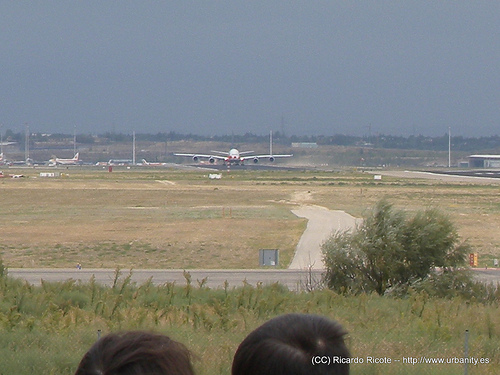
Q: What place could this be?
A: It is a desert.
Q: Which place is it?
A: It is a desert.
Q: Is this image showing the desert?
A: Yes, it is showing the desert.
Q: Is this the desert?
A: Yes, it is the desert.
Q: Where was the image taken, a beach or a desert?
A: It was taken at a desert.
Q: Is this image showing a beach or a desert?
A: It is showing a desert.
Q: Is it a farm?
A: No, it is a desert.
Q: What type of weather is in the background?
A: It is clear.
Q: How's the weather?
A: It is clear.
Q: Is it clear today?
A: Yes, it is clear.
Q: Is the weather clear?
A: Yes, it is clear.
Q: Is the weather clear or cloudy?
A: It is clear.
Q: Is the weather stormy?
A: No, it is clear.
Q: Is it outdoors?
A: Yes, it is outdoors.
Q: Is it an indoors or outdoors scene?
A: It is outdoors.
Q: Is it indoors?
A: No, it is outdoors.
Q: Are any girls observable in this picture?
A: No, there are no girls.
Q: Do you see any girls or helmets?
A: No, there are no girls or helmets.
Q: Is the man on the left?
A: Yes, the man is on the left of the image.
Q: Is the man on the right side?
A: No, the man is on the left of the image.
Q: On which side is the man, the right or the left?
A: The man is on the left of the image.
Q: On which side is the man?
A: The man is on the left of the image.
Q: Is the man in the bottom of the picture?
A: Yes, the man is in the bottom of the image.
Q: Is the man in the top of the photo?
A: No, the man is in the bottom of the image.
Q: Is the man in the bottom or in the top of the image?
A: The man is in the bottom of the image.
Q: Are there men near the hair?
A: Yes, there is a man near the hair.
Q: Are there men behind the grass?
A: Yes, there is a man behind the grass.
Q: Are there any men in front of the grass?
A: No, the man is behind the grass.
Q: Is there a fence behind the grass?
A: No, there is a man behind the grass.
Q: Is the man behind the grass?
A: Yes, the man is behind the grass.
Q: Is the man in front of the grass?
A: No, the man is behind the grass.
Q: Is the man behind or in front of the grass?
A: The man is behind the grass.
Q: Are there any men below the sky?
A: Yes, there is a man below the sky.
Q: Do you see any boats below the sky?
A: No, there is a man below the sky.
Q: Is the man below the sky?
A: Yes, the man is below the sky.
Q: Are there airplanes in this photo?
A: Yes, there is an airplane.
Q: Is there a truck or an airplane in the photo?
A: Yes, there is an airplane.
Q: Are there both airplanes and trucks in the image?
A: No, there is an airplane but no trucks.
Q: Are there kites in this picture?
A: No, there are no kites.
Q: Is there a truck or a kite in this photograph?
A: No, there are no kites or trucks.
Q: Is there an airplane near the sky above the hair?
A: Yes, there is an airplane near the sky.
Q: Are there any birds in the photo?
A: No, there are no birds.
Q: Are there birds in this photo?
A: No, there are no birds.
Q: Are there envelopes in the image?
A: No, there are no envelopes.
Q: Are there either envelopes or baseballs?
A: No, there are no envelopes or baseballs.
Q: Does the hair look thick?
A: Yes, the hair is thick.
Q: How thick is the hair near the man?
A: The hair is thick.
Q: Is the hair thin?
A: No, the hair is thick.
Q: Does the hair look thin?
A: No, the hair is thick.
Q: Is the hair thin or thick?
A: The hair is thick.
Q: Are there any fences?
A: No, there are no fences.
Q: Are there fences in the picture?
A: No, there are no fences.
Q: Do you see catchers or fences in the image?
A: No, there are no fences or catchers.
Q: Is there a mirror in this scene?
A: No, there are no mirrors.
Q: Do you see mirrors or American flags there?
A: No, there are no mirrors or American flags.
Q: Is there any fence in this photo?
A: No, there are no fences.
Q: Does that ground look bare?
A: Yes, the ground is bare.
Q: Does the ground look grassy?
A: No, the ground is bare.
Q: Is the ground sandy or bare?
A: The ground is bare.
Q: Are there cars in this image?
A: No, there are no cars.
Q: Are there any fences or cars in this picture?
A: No, there are no cars or fences.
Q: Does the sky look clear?
A: Yes, the sky is clear.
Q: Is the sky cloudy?
A: No, the sky is clear.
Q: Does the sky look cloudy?
A: No, the sky is clear.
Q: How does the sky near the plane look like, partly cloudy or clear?
A: The sky is clear.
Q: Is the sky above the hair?
A: Yes, the sky is above the hair.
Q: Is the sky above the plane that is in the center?
A: Yes, the sky is above the plane.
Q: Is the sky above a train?
A: No, the sky is above the plane.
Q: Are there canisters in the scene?
A: No, there are no canisters.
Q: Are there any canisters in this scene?
A: No, there are no canisters.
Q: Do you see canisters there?
A: No, there are no canisters.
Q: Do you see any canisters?
A: No, there are no canisters.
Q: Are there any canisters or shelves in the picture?
A: No, there are no canisters or shelves.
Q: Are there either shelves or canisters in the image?
A: No, there are no canisters or shelves.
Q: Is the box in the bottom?
A: Yes, the box is in the bottom of the image.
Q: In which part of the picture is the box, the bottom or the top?
A: The box is in the bottom of the image.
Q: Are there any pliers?
A: No, there are no pliers.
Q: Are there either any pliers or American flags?
A: No, there are no pliers or American flags.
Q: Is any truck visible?
A: No, there are no trucks.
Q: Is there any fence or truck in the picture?
A: No, there are no trucks or fences.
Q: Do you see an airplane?
A: Yes, there is an airplane.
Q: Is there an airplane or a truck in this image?
A: Yes, there is an airplane.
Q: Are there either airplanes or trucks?
A: Yes, there is an airplane.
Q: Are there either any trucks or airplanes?
A: Yes, there is an airplane.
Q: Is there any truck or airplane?
A: Yes, there is an airplane.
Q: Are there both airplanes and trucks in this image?
A: No, there is an airplane but no trucks.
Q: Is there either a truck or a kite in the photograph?
A: No, there are no trucks or kites.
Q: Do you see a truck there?
A: No, there are no trucks.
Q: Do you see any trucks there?
A: No, there are no trucks.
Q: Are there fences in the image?
A: No, there are no fences.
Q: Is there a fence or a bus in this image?
A: No, there are no fences or buses.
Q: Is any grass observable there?
A: Yes, there is grass.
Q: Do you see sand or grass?
A: Yes, there is grass.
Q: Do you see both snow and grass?
A: No, there is grass but no snow.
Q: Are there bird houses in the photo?
A: No, there are no bird houses.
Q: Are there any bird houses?
A: No, there are no bird houses.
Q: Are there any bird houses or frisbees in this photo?
A: No, there are no bird houses or frisbees.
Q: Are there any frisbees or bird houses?
A: No, there are no bird houses or frisbees.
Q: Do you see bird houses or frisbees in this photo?
A: No, there are no bird houses or frisbees.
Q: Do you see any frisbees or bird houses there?
A: No, there are no bird houses or frisbees.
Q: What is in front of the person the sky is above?
A: The grass is in front of the man.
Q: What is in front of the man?
A: The grass is in front of the man.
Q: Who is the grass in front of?
A: The grass is in front of the man.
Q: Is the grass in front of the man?
A: Yes, the grass is in front of the man.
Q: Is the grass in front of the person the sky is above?
A: Yes, the grass is in front of the man.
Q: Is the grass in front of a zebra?
A: No, the grass is in front of the man.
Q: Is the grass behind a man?
A: No, the grass is in front of a man.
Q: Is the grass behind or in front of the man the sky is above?
A: The grass is in front of the man.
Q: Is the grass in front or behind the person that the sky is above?
A: The grass is in front of the man.